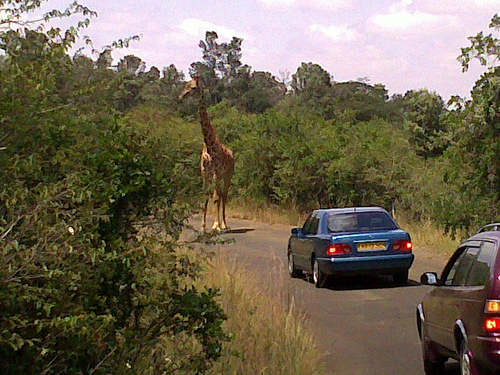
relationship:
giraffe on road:
[176, 73, 231, 236] [138, 202, 448, 374]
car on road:
[287, 207, 415, 288] [153, 216, 440, 373]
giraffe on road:
[179, 72, 234, 236] [167, 200, 456, 367]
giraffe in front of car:
[179, 72, 234, 236] [287, 207, 415, 288]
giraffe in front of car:
[179, 72, 234, 236] [289, 197, 413, 283]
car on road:
[287, 207, 415, 288] [134, 207, 496, 374]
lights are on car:
[325, 236, 429, 267] [271, 174, 413, 308]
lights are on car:
[326, 242, 352, 255] [238, 147, 425, 327]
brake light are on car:
[325, 240, 355, 261] [287, 207, 415, 288]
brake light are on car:
[390, 238, 413, 251] [287, 207, 415, 288]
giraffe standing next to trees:
[176, 73, 231, 236] [0, 0, 230, 375]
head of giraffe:
[179, 71, 202, 101] [179, 72, 234, 236]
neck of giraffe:
[184, 95, 221, 148] [109, 42, 364, 333]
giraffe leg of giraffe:
[201, 180, 209, 227] [179, 72, 234, 236]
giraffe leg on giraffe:
[192, 182, 214, 240] [179, 70, 242, 240]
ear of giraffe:
[193, 77, 202, 89] [179, 72, 234, 236]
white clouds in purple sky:
[296, 11, 365, 55] [141, 4, 471, 54]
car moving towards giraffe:
[261, 201, 434, 296] [171, 62, 266, 252]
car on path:
[416, 222, 500, 375] [165, 202, 498, 372]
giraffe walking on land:
[179, 72, 234, 236] [0, 204, 499, 374]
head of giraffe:
[161, 72, 218, 102] [155, 70, 262, 277]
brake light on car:
[326, 243, 352, 254] [271, 174, 413, 308]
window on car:
[326, 210, 400, 234] [291, 207, 413, 287]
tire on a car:
[289, 254, 303, 277] [271, 179, 445, 314]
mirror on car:
[289, 222, 301, 237] [287, 207, 415, 288]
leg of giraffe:
[212, 175, 221, 234] [179, 72, 234, 236]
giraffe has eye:
[179, 72, 234, 236] [190, 85, 197, 92]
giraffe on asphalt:
[179, 72, 234, 236] [184, 213, 285, 259]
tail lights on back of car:
[326, 237, 412, 257] [287, 207, 415, 288]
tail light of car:
[483, 298, 499, 340] [416, 222, 500, 375]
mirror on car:
[414, 269, 442, 292] [398, 221, 496, 373]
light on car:
[393, 239, 413, 250] [278, 205, 418, 284]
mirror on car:
[291, 228, 297, 234] [287, 207, 415, 288]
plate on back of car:
[348, 236, 402, 255] [294, 215, 423, 276]